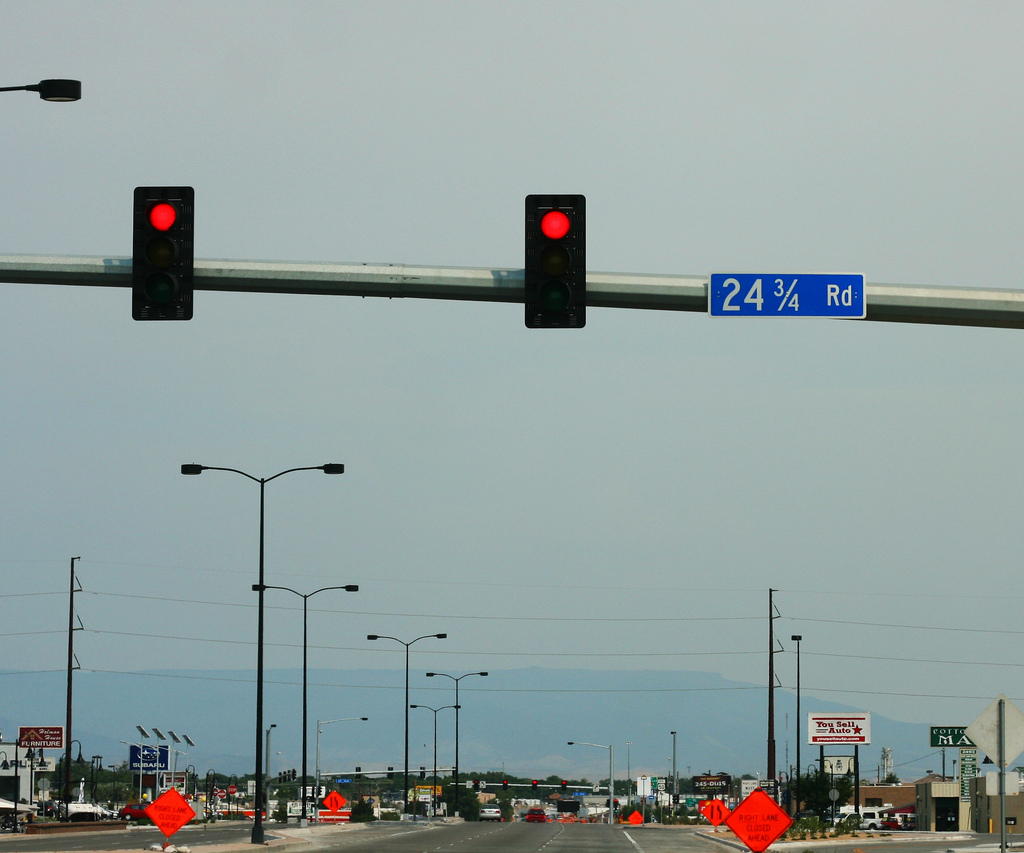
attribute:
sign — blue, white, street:
[695, 243, 896, 354]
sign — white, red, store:
[802, 696, 869, 766]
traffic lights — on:
[498, 167, 629, 335]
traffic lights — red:
[100, 162, 631, 363]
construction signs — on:
[707, 762, 816, 851]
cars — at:
[458, 791, 576, 839]